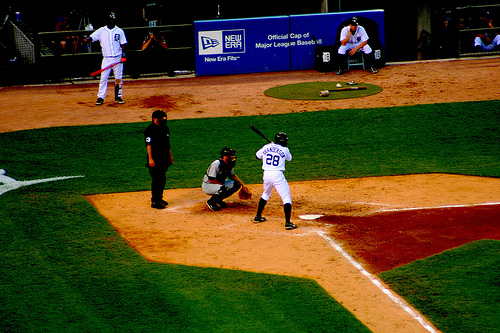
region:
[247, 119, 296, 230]
Baseball player with a bat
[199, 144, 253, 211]
Baseball player with a catchers mitt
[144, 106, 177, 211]
Baseball player in black clothing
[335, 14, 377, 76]
Baseball player sitting on a chair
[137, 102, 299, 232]
Men playing baseball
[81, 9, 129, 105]
Man in a white uniform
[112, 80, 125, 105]
Brace on a man's leg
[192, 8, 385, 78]
Blue mats with white lettering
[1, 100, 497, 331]
Green baseball diamond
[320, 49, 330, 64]
White Tigers logo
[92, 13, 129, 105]
player wearing white and blue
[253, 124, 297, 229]
player number twenty eight at bat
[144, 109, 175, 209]
umpire in black behind catcher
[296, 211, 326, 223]
white home plate at field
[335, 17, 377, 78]
player in white sitting waiting to bat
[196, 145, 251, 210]
catcher in grey behind batter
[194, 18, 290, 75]
white and blue banner at dugout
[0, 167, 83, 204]
symbol in white on green grass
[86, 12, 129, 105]
player holding red bat with red glove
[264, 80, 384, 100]
bat and chalk on practice circle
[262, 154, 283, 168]
the number 28 on a batter's back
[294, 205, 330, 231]
white home plate on a baseball diamond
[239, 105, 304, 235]
batter in a uniform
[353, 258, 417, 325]
white chalk on a baseball diamond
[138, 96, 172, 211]
umpire standing behind a catcher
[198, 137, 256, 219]
catcher between an umpire and batter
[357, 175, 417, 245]
brown dirt on a baseball diamond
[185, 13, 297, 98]
blue and white advertisement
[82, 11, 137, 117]
batter waiting on deck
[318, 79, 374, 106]
baseball bat on the ground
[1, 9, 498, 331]
baseball players on a field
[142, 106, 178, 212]
umpire on a baseball field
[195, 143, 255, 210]
catcher on a baseball field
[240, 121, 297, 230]
player at bat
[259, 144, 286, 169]
name and number on the back of a jersey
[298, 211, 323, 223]
white homeplate on a baseball fiels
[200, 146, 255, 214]
baseball catcher in position to catch a ball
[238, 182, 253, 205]
gloves on a baseball catcher's hand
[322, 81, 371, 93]
baseball and bat laying on a field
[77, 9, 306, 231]
four people on a field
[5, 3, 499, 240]
a baseball game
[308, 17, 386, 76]
a baseball player waiting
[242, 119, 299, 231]
a batter waiting for the ball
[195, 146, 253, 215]
the catcher in position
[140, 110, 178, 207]
a umpire watching the game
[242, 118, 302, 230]
a baseball player with a bat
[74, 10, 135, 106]
a baseball player holding an orange bat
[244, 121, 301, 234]
a baseball player wearing a white uniform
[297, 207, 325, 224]
the white home plate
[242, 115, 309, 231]
a baseball player wearing a helmet